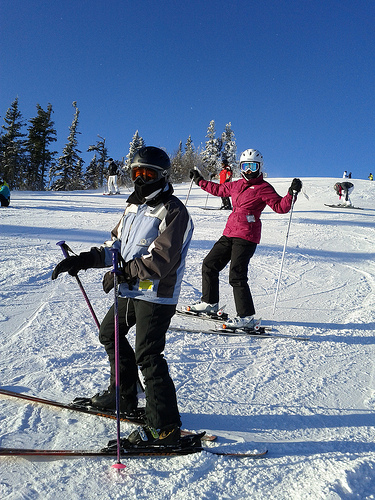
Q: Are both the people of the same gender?
A: No, they are both male and female.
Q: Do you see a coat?
A: Yes, there is a coat.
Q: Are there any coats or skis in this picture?
A: Yes, there is a coat.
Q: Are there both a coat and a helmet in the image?
A: Yes, there are both a coat and a helmet.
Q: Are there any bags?
A: No, there are no bags.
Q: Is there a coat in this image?
A: Yes, there is a coat.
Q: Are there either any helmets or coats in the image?
A: Yes, there is a coat.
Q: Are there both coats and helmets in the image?
A: Yes, there are both a coat and a helmet.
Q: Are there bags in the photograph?
A: No, there are no bags.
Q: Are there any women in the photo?
A: Yes, there is a woman.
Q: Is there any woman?
A: Yes, there is a woman.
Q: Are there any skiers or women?
A: Yes, there is a woman.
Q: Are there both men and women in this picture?
A: Yes, there are both a woman and a man.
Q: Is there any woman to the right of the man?
A: Yes, there is a woman to the right of the man.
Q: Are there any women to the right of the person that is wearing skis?
A: Yes, there is a woman to the right of the man.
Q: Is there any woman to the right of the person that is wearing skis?
A: Yes, there is a woman to the right of the man.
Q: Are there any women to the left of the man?
A: No, the woman is to the right of the man.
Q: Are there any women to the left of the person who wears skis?
A: No, the woman is to the right of the man.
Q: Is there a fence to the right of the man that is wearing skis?
A: No, there is a woman to the right of the man.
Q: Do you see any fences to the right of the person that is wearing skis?
A: No, there is a woman to the right of the man.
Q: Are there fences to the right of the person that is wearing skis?
A: No, there is a woman to the right of the man.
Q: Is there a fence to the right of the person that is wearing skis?
A: No, there is a woman to the right of the man.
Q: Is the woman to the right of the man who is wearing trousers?
A: Yes, the woman is to the right of the man.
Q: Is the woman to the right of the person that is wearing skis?
A: Yes, the woman is to the right of the man.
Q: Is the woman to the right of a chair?
A: No, the woman is to the right of the man.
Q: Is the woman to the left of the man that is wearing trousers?
A: No, the woman is to the right of the man.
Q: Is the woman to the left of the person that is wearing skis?
A: No, the woman is to the right of the man.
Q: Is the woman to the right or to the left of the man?
A: The woman is to the right of the man.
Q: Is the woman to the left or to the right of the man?
A: The woman is to the right of the man.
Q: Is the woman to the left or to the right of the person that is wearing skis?
A: The woman is to the right of the man.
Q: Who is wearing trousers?
A: The woman is wearing trousers.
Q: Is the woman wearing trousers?
A: Yes, the woman is wearing trousers.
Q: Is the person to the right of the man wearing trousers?
A: Yes, the woman is wearing trousers.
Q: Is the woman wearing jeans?
A: No, the woman is wearing trousers.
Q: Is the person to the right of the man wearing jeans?
A: No, the woman is wearing trousers.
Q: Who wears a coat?
A: The woman wears a coat.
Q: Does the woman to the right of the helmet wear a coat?
A: Yes, the woman wears a coat.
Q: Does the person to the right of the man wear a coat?
A: Yes, the woman wears a coat.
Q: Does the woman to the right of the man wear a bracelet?
A: No, the woman wears a coat.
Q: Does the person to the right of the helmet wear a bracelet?
A: No, the woman wears a coat.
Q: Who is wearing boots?
A: The woman is wearing boots.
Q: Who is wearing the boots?
A: The woman is wearing boots.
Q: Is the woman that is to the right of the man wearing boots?
A: Yes, the woman is wearing boots.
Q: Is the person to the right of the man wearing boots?
A: Yes, the woman is wearing boots.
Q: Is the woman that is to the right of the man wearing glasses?
A: No, the woman is wearing boots.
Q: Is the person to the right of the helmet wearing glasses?
A: No, the woman is wearing boots.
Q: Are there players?
A: No, there are no players.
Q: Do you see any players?
A: No, there are no players.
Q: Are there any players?
A: No, there are no players.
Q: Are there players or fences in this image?
A: No, there are no players or fences.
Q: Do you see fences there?
A: No, there are no fences.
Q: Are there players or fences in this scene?
A: No, there are no fences or players.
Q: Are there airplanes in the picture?
A: No, there are no airplanes.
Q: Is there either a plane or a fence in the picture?
A: No, there are no airplanes or fences.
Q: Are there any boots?
A: Yes, there are boots.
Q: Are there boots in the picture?
A: Yes, there are boots.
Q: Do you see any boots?
A: Yes, there are boots.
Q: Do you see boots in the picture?
A: Yes, there are boots.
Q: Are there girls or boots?
A: Yes, there are boots.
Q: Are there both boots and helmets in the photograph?
A: Yes, there are both boots and a helmet.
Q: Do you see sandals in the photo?
A: No, there are no sandals.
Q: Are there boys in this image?
A: No, there are no boys.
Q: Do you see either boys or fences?
A: No, there are no boys or fences.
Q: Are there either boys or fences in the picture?
A: No, there are no boys or fences.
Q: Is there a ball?
A: No, there are no balls.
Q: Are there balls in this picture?
A: No, there are no balls.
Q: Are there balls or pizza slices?
A: No, there are no balls or pizza slices.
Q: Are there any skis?
A: Yes, there are skis.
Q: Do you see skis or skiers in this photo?
A: Yes, there are skis.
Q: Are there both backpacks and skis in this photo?
A: No, there are skis but no backpacks.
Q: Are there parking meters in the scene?
A: No, there are no parking meters.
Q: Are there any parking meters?
A: No, there are no parking meters.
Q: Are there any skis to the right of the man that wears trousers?
A: Yes, there are skis to the right of the man.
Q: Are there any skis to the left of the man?
A: No, the skis are to the right of the man.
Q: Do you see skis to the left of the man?
A: No, the skis are to the right of the man.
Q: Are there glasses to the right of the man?
A: No, there are skis to the right of the man.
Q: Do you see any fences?
A: No, there are no fences.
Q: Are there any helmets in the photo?
A: Yes, there is a helmet.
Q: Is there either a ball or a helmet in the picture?
A: Yes, there is a helmet.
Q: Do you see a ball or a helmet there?
A: Yes, there is a helmet.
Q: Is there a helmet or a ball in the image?
A: Yes, there is a helmet.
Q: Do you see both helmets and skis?
A: Yes, there are both a helmet and skis.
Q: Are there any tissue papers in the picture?
A: No, there are no tissue papers.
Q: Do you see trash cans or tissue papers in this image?
A: No, there are no tissue papers or trash cans.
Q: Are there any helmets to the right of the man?
A: Yes, there is a helmet to the right of the man.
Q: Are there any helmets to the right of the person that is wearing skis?
A: Yes, there is a helmet to the right of the man.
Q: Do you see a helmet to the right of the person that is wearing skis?
A: Yes, there is a helmet to the right of the man.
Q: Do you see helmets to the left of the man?
A: No, the helmet is to the right of the man.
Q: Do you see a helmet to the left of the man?
A: No, the helmet is to the right of the man.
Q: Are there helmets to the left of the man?
A: No, the helmet is to the right of the man.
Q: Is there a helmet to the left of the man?
A: No, the helmet is to the right of the man.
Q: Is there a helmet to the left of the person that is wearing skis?
A: No, the helmet is to the right of the man.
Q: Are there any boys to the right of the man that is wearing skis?
A: No, there is a helmet to the right of the man.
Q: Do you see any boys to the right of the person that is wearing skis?
A: No, there is a helmet to the right of the man.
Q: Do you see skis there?
A: Yes, there are skis.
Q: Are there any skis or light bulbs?
A: Yes, there are skis.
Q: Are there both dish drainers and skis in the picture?
A: No, there are skis but no dish drainers.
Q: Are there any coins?
A: No, there are no coins.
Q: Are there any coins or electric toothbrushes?
A: No, there are no coins or electric toothbrushes.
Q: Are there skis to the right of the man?
A: Yes, there are skis to the right of the man.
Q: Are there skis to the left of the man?
A: No, the skis are to the right of the man.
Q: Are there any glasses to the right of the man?
A: No, there are skis to the right of the man.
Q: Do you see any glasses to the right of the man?
A: No, there are skis to the right of the man.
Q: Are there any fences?
A: No, there are no fences.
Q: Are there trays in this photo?
A: No, there are no trays.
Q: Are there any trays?
A: No, there are no trays.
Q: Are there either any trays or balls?
A: No, there are no trays or balls.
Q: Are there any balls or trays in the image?
A: No, there are no trays or balls.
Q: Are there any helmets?
A: Yes, there is a helmet.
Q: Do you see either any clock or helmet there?
A: Yes, there is a helmet.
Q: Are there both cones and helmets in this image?
A: No, there is a helmet but no cones.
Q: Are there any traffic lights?
A: No, there are no traffic lights.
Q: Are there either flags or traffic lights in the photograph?
A: No, there are no traffic lights or flags.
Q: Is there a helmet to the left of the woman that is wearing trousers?
A: Yes, there is a helmet to the left of the woman.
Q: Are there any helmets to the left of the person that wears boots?
A: Yes, there is a helmet to the left of the woman.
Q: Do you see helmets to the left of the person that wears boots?
A: Yes, there is a helmet to the left of the woman.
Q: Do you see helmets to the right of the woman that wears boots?
A: No, the helmet is to the left of the woman.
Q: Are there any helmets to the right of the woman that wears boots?
A: No, the helmet is to the left of the woman.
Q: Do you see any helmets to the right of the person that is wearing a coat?
A: No, the helmet is to the left of the woman.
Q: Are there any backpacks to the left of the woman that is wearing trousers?
A: No, there is a helmet to the left of the woman.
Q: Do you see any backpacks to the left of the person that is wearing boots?
A: No, there is a helmet to the left of the woman.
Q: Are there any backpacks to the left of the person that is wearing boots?
A: No, there is a helmet to the left of the woman.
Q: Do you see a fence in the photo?
A: No, there are no fences.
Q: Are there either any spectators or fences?
A: No, there are no fences or spectators.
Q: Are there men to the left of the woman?
A: Yes, there is a man to the left of the woman.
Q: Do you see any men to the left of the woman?
A: Yes, there is a man to the left of the woman.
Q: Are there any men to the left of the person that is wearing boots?
A: Yes, there is a man to the left of the woman.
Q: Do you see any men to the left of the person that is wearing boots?
A: Yes, there is a man to the left of the woman.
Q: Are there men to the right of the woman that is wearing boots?
A: No, the man is to the left of the woman.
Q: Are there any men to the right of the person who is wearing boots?
A: No, the man is to the left of the woman.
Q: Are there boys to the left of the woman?
A: No, there is a man to the left of the woman.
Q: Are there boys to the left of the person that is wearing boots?
A: No, there is a man to the left of the woman.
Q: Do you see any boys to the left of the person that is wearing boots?
A: No, there is a man to the left of the woman.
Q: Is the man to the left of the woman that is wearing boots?
A: Yes, the man is to the left of the woman.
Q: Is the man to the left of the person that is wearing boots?
A: Yes, the man is to the left of the woman.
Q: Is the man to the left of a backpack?
A: No, the man is to the left of the woman.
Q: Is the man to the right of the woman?
A: No, the man is to the left of the woman.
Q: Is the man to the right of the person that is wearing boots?
A: No, the man is to the left of the woman.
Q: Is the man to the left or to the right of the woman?
A: The man is to the left of the woman.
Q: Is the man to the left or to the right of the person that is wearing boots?
A: The man is to the left of the woman.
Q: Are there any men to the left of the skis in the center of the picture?
A: Yes, there is a man to the left of the skis.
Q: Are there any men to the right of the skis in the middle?
A: No, the man is to the left of the skis.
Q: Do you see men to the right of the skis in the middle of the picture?
A: No, the man is to the left of the skis.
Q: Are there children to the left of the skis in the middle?
A: No, there is a man to the left of the skis.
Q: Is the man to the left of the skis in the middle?
A: Yes, the man is to the left of the skis.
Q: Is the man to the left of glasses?
A: No, the man is to the left of the skis.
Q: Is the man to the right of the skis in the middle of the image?
A: No, the man is to the left of the skis.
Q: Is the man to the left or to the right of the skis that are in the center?
A: The man is to the left of the skis.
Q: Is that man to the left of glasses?
A: No, the man is to the left of the skis.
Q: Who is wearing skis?
A: The man is wearing skis.